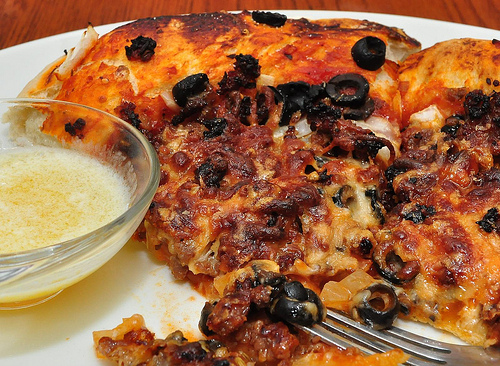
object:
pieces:
[136, 54, 424, 272]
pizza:
[3, 10, 500, 365]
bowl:
[0, 99, 162, 310]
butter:
[4, 155, 89, 235]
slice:
[3, 10, 400, 365]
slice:
[399, 19, 496, 299]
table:
[6, 1, 498, 20]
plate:
[0, 8, 499, 365]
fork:
[290, 292, 481, 364]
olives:
[270, 280, 323, 327]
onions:
[406, 104, 444, 132]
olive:
[349, 35, 389, 72]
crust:
[101, 8, 399, 76]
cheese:
[191, 176, 320, 252]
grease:
[117, 278, 187, 312]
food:
[0, 9, 498, 364]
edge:
[57, 10, 420, 79]